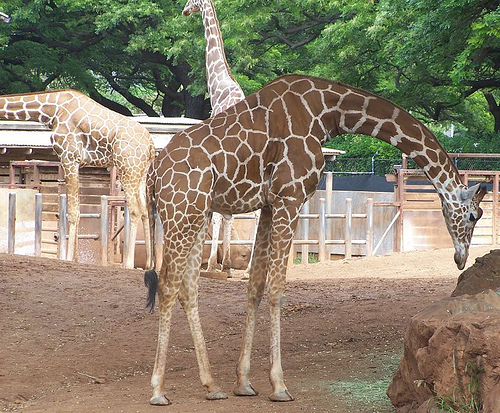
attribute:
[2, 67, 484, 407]
two giraffes — back to back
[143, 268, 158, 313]
black hairs — on the tail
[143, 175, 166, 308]
giraffe tail — hanging down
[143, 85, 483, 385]
giraffe — side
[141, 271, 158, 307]
hair — black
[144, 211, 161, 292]
tail — giraffe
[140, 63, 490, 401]
giraffe — standing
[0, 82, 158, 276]
giraffe — standing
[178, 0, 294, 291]
giraffe — standing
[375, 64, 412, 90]
leaves — green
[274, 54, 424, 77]
leaves — green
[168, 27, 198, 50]
leaves — green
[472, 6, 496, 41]
leaves — green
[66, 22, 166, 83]
leaves — green